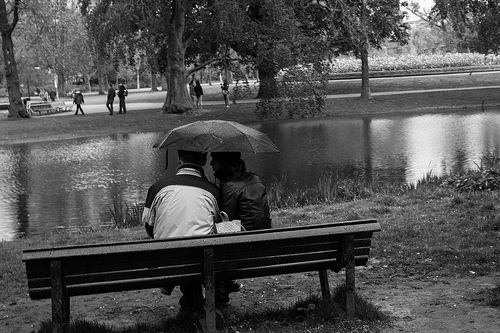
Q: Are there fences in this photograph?
A: No, there are no fences.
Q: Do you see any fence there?
A: No, there are no fences.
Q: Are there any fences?
A: No, there are no fences.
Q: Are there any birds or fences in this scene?
A: No, there are no fences or birds.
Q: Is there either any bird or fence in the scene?
A: No, there are no fences or birds.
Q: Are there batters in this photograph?
A: No, there are no batters.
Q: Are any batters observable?
A: No, there are no batters.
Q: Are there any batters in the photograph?
A: No, there are no batters.